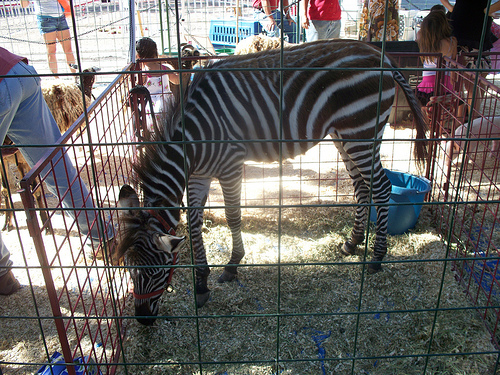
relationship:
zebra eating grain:
[120, 38, 443, 325] [121, 199, 496, 373]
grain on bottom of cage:
[121, 199, 496, 373] [22, 53, 499, 373]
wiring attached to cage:
[1, 1, 499, 373] [22, 53, 499, 373]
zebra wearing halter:
[120, 38, 443, 325] [130, 201, 177, 301]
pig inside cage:
[442, 117, 499, 167] [438, 52, 500, 205]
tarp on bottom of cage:
[309, 331, 334, 370] [22, 53, 499, 373]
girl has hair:
[414, 5, 462, 104] [416, 4, 451, 62]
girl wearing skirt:
[414, 5, 462, 104] [418, 76, 453, 95]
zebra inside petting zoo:
[120, 38, 443, 325] [0, 1, 500, 373]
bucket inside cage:
[361, 169, 432, 232] [22, 53, 499, 373]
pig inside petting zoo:
[442, 117, 499, 167] [0, 1, 500, 373]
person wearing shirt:
[0, 47, 125, 295] [0, 47, 28, 82]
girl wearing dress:
[134, 38, 197, 135] [145, 66, 178, 134]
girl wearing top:
[402, 5, 467, 111] [449, 1, 497, 50]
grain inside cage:
[121, 199, 496, 373] [22, 53, 499, 373]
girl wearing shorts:
[402, 5, 467, 111] [458, 47, 491, 73]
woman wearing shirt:
[21, 0, 79, 81] [33, 0, 65, 18]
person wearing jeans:
[0, 47, 125, 295] [0, 63, 116, 273]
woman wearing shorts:
[21, 0, 79, 81] [39, 15, 71, 32]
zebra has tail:
[120, 38, 443, 325] [391, 66, 433, 170]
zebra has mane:
[120, 38, 443, 325] [129, 69, 195, 181]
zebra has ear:
[120, 38, 443, 325] [116, 183, 141, 214]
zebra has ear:
[120, 38, 443, 325] [160, 234, 189, 257]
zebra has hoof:
[120, 38, 443, 325] [196, 292, 211, 309]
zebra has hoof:
[120, 38, 443, 325] [218, 269, 238, 284]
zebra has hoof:
[120, 38, 443, 325] [341, 243, 352, 256]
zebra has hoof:
[120, 38, 443, 325] [364, 265, 378, 276]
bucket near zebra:
[361, 169, 432, 232] [120, 38, 443, 325]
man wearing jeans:
[0, 47, 125, 295] [0, 63, 116, 273]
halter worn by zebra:
[130, 201, 177, 301] [120, 38, 443, 325]